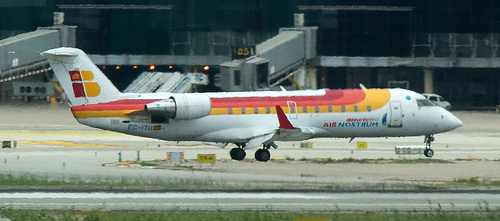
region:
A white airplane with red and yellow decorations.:
[39, 46, 461, 144]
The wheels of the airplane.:
[221, 142, 443, 161]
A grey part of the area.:
[118, 0, 497, 87]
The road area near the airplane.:
[117, 191, 399, 211]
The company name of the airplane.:
[322, 117, 384, 132]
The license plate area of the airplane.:
[121, 120, 163, 131]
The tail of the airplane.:
[33, 46, 114, 103]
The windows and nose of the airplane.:
[388, 87, 465, 134]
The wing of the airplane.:
[192, 105, 325, 141]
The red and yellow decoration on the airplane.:
[226, 94, 282, 118]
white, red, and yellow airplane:
[40, 46, 460, 162]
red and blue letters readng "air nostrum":
[320, 117, 382, 129]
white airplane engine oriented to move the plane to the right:
[141, 93, 215, 122]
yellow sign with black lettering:
[196, 152, 217, 167]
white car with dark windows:
[417, 91, 452, 111]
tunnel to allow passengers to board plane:
[216, 22, 318, 99]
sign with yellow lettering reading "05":
[232, 44, 258, 61]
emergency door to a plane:
[286, 99, 302, 120]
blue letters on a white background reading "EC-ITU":
[126, 122, 163, 134]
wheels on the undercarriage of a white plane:
[225, 137, 282, 163]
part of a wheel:
[436, 148, 443, 155]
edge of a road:
[245, 193, 253, 210]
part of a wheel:
[256, 157, 262, 167]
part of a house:
[383, 4, 407, 45]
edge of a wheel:
[418, 138, 421, 158]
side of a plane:
[269, 147, 271, 149]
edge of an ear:
[261, 121, 263, 148]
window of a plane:
[410, 92, 437, 109]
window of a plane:
[363, 101, 379, 116]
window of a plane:
[348, 103, 360, 118]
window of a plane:
[330, 100, 349, 121]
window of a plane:
[305, 101, 321, 115]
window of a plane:
[285, 100, 302, 121]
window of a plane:
[262, 99, 277, 128]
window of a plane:
[245, 101, 265, 132]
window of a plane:
[239, 97, 257, 120]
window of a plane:
[217, 101, 239, 128]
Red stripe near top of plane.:
[241, 92, 271, 100]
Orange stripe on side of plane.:
[338, 87, 350, 107]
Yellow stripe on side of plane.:
[313, 104, 351, 117]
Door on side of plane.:
[283, 94, 315, 142]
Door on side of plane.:
[383, 103, 415, 147]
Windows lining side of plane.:
[215, 105, 370, 113]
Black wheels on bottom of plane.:
[248, 148, 281, 168]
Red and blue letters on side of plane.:
[325, 117, 391, 144]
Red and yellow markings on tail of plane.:
[68, 72, 100, 100]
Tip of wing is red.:
[271, 111, 291, 128]